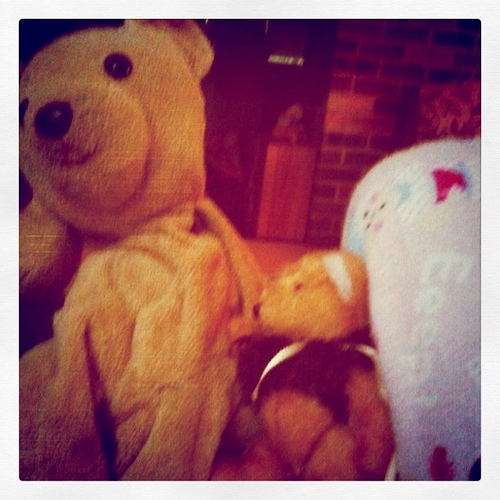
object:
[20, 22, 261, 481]
teddy bear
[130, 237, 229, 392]
arm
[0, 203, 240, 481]
body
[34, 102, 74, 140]
nose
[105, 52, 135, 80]
eye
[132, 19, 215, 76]
ear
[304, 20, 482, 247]
wall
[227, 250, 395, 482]
cub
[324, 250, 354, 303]
ear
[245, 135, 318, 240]
speaker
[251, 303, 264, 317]
nose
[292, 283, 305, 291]
eye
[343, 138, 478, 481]
cloth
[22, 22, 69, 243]
right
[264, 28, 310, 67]
sign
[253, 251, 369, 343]
head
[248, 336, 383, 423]
shirt